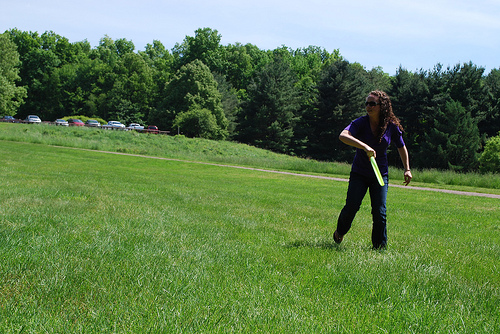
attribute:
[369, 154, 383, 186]
frisbee — lime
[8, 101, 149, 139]
cars — parked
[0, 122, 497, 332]
grass — green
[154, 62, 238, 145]
tree — tall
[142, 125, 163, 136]
car — burgundy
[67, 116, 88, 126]
car — red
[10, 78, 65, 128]
car — silver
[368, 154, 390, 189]
frisbee — yellow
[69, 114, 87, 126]
sedan — red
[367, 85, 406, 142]
hair — long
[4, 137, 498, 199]
path — small